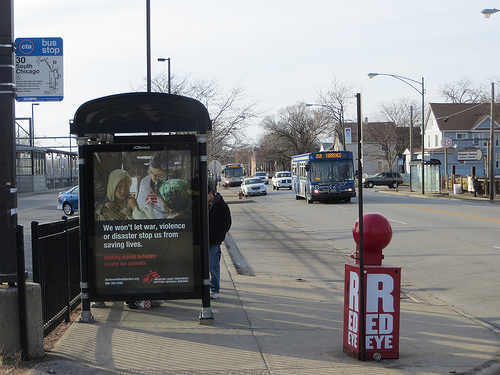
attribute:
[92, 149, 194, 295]
poster — black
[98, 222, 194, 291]
writing — white, red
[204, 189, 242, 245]
jacket — black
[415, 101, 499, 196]
house — light blue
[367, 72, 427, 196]
light pole — tall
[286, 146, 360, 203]
bus — Blue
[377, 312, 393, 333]
white d — letter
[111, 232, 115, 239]
white d — letter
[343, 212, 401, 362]
post — red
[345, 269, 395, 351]
writing — white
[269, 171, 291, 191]
truck — white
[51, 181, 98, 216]
car — parked, blue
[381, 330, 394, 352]
letter — white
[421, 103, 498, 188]
building — part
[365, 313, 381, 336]
letter — white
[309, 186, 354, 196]
headlights — on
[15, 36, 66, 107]
sign — rectangular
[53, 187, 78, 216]
blue car — part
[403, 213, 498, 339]
street — part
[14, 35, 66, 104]
stop sign — blue, white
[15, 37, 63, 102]
sign — part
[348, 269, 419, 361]
letter — white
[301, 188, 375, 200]
headlights — on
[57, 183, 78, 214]
car — blue